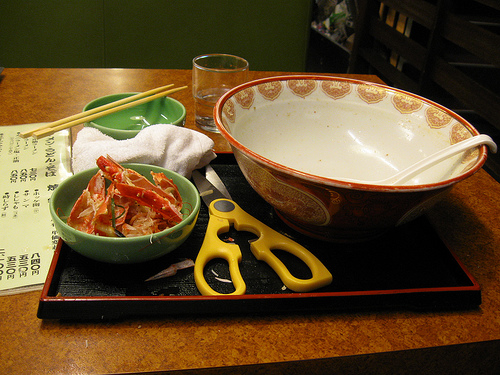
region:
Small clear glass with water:
[179, 41, 256, 146]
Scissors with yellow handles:
[188, 151, 340, 330]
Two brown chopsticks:
[10, 77, 192, 144]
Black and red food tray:
[37, 132, 485, 326]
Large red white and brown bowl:
[203, 68, 493, 241]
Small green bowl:
[83, 83, 187, 148]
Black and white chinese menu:
[3, 117, 80, 316]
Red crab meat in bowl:
[65, 148, 188, 252]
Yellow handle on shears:
[195, 183, 340, 324]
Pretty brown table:
[2, 58, 498, 374]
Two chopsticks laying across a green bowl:
[18, 83, 189, 140]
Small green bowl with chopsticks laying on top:
[88, 88, 188, 135]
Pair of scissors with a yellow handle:
[195, 168, 331, 297]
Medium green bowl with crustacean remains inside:
[50, 151, 198, 259]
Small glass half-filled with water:
[189, 48, 254, 134]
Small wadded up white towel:
[72, 125, 217, 176]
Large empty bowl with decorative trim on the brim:
[210, 74, 485, 231]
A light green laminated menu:
[0, 116, 73, 296]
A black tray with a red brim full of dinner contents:
[42, 148, 477, 320]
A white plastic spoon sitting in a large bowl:
[337, 131, 499, 187]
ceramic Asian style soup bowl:
[211, 75, 489, 222]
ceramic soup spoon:
[377, 136, 496, 184]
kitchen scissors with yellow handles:
[190, 166, 335, 294]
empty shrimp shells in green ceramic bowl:
[52, 162, 200, 260]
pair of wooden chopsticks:
[19, 82, 190, 139]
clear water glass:
[192, 53, 248, 131]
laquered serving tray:
[38, 151, 481, 321]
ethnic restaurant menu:
[0, 122, 70, 294]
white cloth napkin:
[70, 126, 214, 177]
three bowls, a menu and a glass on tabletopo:
[0, 67, 499, 370]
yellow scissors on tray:
[187, 174, 304, 314]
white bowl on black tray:
[223, 51, 456, 243]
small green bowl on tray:
[49, 164, 189, 249]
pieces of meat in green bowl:
[83, 150, 173, 241]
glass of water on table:
[168, 45, 239, 129]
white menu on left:
[10, 120, 55, 295]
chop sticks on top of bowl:
[34, 75, 188, 150]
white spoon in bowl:
[360, 113, 487, 190]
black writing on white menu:
[11, 226, 63, 284]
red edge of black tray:
[42, 289, 316, 320]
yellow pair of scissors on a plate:
[171, 154, 340, 294]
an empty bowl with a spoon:
[212, 74, 491, 237]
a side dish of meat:
[42, 153, 199, 270]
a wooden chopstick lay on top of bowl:
[14, 74, 189, 152]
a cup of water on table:
[182, 54, 259, 135]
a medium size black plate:
[42, 132, 487, 319]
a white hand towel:
[63, 114, 223, 191]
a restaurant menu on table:
[2, 114, 89, 289]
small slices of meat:
[54, 145, 182, 242]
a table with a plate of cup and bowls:
[0, 63, 490, 371]